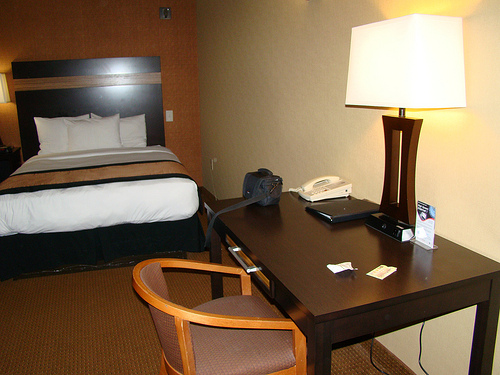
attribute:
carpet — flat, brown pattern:
[8, 182, 393, 367]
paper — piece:
[325, 257, 354, 276]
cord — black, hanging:
[404, 314, 448, 374]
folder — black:
[308, 196, 383, 223]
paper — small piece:
[325, 260, 353, 273]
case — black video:
[196, 167, 283, 247]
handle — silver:
[227, 244, 260, 276]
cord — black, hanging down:
[203, 164, 311, 250]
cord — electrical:
[416, 320, 437, 373]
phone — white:
[297, 173, 354, 198]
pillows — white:
[44, 123, 159, 158]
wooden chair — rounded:
[129, 248, 306, 373]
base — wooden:
[372, 107, 427, 227]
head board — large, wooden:
[12, 63, 161, 148]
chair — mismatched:
[126, 252, 315, 374]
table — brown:
[206, 178, 498, 374]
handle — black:
[193, 186, 258, 243]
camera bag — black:
[237, 164, 284, 211]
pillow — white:
[25, 105, 156, 157]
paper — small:
[323, 256, 358, 273]